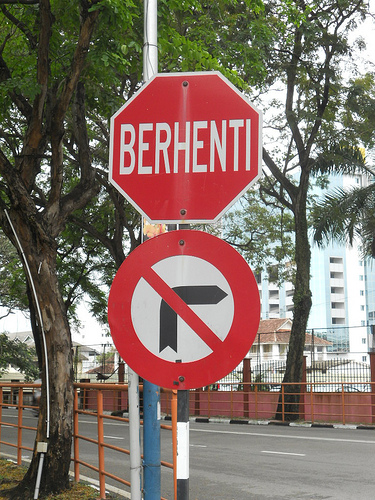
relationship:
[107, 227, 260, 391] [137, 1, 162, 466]
sign on pole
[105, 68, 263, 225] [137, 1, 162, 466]
sign on pole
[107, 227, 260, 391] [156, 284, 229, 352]
sign has arrow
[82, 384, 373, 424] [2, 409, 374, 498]
wall by road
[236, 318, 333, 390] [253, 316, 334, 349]
house with roof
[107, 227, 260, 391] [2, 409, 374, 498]
sign on road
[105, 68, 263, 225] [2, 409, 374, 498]
sign on road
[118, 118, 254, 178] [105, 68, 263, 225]
behrenti on sign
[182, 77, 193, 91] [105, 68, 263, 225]
screw on sign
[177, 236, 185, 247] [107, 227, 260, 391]
screw on sign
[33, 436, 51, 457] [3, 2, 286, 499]
electrical box on tree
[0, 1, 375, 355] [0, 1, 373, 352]
clouds in sky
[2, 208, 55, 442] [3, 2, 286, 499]
wire on tree